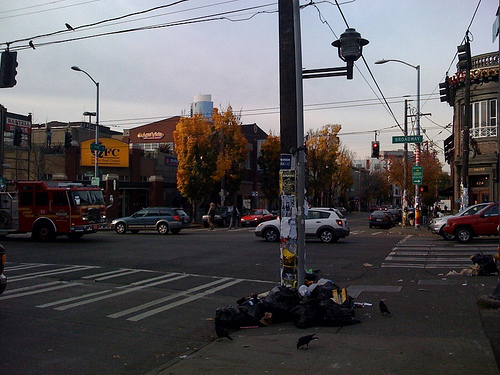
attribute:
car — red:
[442, 206, 499, 243]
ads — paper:
[275, 153, 306, 291]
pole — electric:
[286, 3, 308, 318]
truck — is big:
[19, 176, 106, 240]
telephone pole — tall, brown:
[278, 2, 305, 289]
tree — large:
[200, 110, 400, 284]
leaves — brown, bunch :
[170, 102, 253, 204]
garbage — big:
[222, 277, 383, 329]